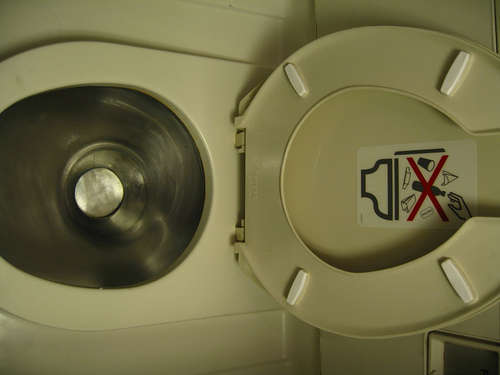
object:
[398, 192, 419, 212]
paper bag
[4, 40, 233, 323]
seat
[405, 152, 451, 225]
red x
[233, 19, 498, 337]
toilet backing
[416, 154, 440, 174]
cup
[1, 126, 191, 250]
metal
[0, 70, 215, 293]
bowl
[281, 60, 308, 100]
bumper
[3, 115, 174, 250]
inside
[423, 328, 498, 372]
trash can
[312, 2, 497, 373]
wall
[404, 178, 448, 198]
bottle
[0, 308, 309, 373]
white wall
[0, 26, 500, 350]
toilet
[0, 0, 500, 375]
airplane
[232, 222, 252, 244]
screw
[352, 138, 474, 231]
picture